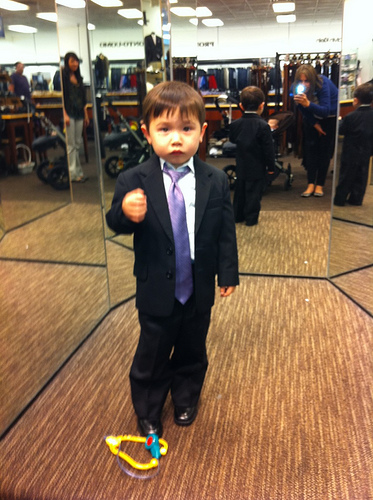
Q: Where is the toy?
A: In front of the boy.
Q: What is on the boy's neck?
A: A purple tie.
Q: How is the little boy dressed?
A: In a suit?.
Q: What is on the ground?
A: A toy.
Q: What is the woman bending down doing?
A: Taking a picture.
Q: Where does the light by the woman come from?
A: The camera flash.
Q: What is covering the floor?
A: Carpeting.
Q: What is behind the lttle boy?
A: Mirrors.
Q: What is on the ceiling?
A: Lights.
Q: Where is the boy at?
A: Department store.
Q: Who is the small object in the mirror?
A: A young boy.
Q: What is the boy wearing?
A: A tuxedo.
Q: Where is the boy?
A: In a store.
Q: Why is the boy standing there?
A: He is posing for a picture.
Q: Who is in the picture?
A: Boy.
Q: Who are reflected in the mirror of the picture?
A: People.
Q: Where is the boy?
A: Department store.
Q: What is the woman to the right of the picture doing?
A: Photographing the boy.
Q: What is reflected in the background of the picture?
A: Clothing.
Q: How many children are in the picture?
A: One.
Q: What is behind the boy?
A: Mirror.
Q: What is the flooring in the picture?
A: Carpet.